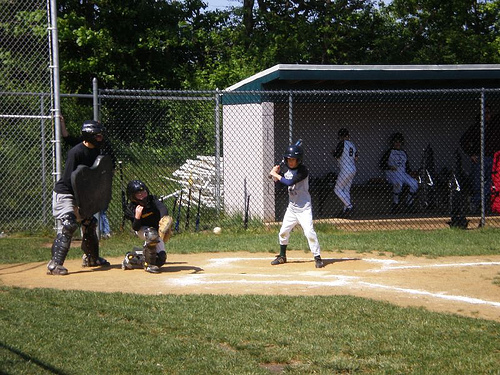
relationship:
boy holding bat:
[272, 141, 331, 273] [268, 140, 302, 180]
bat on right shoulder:
[268, 140, 302, 180] [269, 163, 311, 186]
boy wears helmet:
[272, 141, 331, 273] [285, 146, 306, 162]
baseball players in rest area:
[333, 127, 499, 213] [272, 99, 500, 217]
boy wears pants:
[272, 141, 331, 273] [280, 209, 322, 257]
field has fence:
[9, 234, 497, 375] [7, 91, 498, 239]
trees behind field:
[9, 5, 495, 61] [9, 234, 497, 375]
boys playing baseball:
[38, 127, 328, 272] [210, 226, 226, 236]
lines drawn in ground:
[360, 276, 500, 318] [9, 234, 497, 375]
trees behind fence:
[9, 5, 495, 61] [7, 91, 498, 239]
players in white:
[279, 173, 323, 256] [281, 172, 323, 257]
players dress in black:
[54, 146, 110, 195] [126, 197, 171, 228]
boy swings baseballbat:
[272, 141, 331, 273] [268, 140, 302, 180]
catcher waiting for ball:
[124, 183, 178, 272] [210, 226, 226, 236]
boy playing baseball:
[272, 141, 331, 273] [210, 226, 226, 236]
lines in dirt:
[360, 276, 500, 318] [366, 236, 500, 325]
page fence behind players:
[7, 91, 498, 239] [38, 127, 328, 272]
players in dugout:
[279, 173, 323, 256] [272, 99, 500, 217]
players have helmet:
[279, 173, 323, 256] [285, 146, 306, 162]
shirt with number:
[340, 143, 358, 209] [347, 140, 357, 159]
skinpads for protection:
[144, 228, 166, 250] [142, 221, 173, 255]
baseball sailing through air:
[210, 226, 226, 236] [185, 170, 260, 202]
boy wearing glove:
[116, 179, 171, 275] [154, 213, 177, 242]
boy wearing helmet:
[272, 141, 331, 273] [285, 146, 306, 162]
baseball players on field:
[38, 127, 328, 272] [9, 234, 497, 375]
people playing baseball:
[38, 127, 328, 272] [210, 226, 226, 236]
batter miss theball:
[272, 141, 331, 273] [210, 226, 226, 236]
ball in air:
[210, 226, 226, 236] [185, 170, 260, 202]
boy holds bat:
[272, 141, 331, 273] [268, 140, 302, 180]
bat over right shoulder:
[268, 140, 302, 180] [269, 163, 311, 186]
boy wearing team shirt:
[272, 141, 331, 273] [281, 170, 320, 251]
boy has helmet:
[272, 141, 331, 273] [285, 146, 306, 162]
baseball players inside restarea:
[333, 127, 499, 213] [272, 99, 500, 217]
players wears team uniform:
[279, 173, 323, 256] [272, 141, 331, 273]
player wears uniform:
[272, 141, 331, 273] [267, 168, 331, 245]